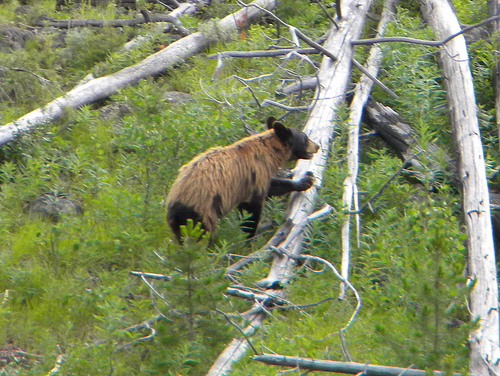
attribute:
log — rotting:
[443, 46, 495, 294]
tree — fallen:
[6, 17, 208, 125]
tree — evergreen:
[135, 216, 243, 373]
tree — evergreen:
[386, 230, 477, 372]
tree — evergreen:
[401, 50, 444, 138]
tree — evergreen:
[32, 1, 283, 125]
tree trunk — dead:
[215, 229, 345, 354]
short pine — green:
[151, 218, 222, 365]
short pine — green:
[390, 245, 464, 358]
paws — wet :
[301, 170, 313, 187]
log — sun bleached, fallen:
[420, 2, 499, 374]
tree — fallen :
[203, 0, 499, 375]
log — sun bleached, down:
[193, 4, 378, 374]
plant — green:
[156, 337, 203, 374]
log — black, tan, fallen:
[253, 29, 495, 204]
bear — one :
[155, 114, 335, 247]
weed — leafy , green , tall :
[408, 65, 460, 363]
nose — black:
[309, 143, 323, 153]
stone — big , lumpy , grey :
[22, 194, 84, 228]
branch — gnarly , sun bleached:
[239, 68, 317, 113]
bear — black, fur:
[133, 72, 350, 287]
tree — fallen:
[345, 47, 499, 232]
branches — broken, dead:
[79, 245, 397, 360]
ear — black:
[270, 123, 295, 147]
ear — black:
[264, 113, 280, 133]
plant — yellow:
[2, 283, 21, 322]